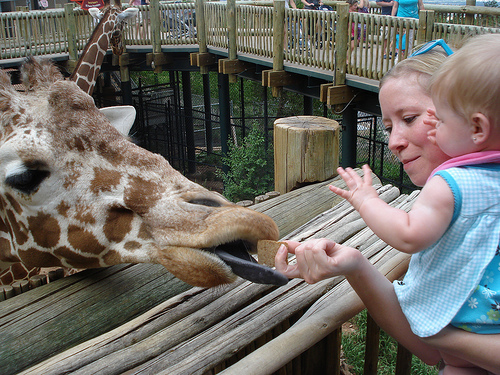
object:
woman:
[273, 45, 500, 375]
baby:
[327, 33, 500, 330]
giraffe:
[1, 63, 287, 287]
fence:
[0, 0, 500, 101]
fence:
[0, 163, 430, 375]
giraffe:
[71, 0, 137, 98]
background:
[0, 0, 500, 176]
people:
[274, 0, 418, 60]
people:
[67, 0, 239, 46]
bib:
[425, 150, 500, 181]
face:
[379, 81, 449, 187]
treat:
[256, 237, 286, 266]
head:
[84, 0, 136, 55]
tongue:
[216, 249, 290, 286]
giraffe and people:
[0, 0, 500, 375]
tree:
[218, 127, 274, 203]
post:
[271, 116, 340, 190]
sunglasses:
[408, 39, 452, 56]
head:
[379, 50, 468, 188]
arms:
[274, 238, 499, 374]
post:
[333, 6, 350, 84]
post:
[272, 2, 284, 72]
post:
[227, 2, 237, 61]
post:
[196, 0, 208, 52]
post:
[149, 0, 161, 49]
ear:
[471, 115, 491, 144]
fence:
[40, 49, 404, 186]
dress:
[389, 169, 500, 337]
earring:
[472, 137, 476, 140]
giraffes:
[0, 5, 291, 287]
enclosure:
[0, 49, 444, 287]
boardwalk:
[0, 0, 500, 90]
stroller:
[279, 10, 313, 56]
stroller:
[314, 9, 343, 49]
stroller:
[160, 2, 198, 39]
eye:
[3, 160, 50, 196]